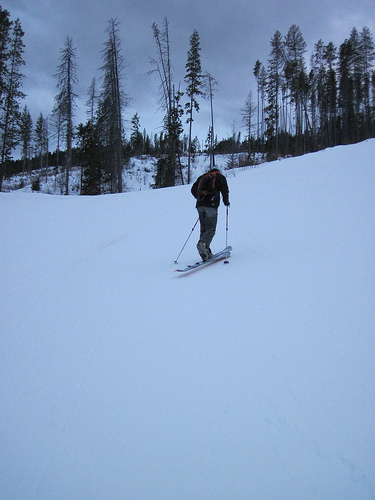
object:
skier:
[192, 168, 231, 261]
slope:
[2, 137, 374, 499]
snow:
[272, 163, 372, 247]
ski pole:
[226, 204, 230, 262]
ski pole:
[175, 218, 200, 263]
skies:
[178, 243, 237, 277]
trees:
[268, 30, 282, 161]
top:
[286, 25, 308, 52]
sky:
[1, 2, 373, 168]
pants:
[196, 206, 218, 251]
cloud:
[33, 88, 147, 134]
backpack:
[198, 171, 221, 201]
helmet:
[210, 167, 219, 171]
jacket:
[191, 174, 230, 210]